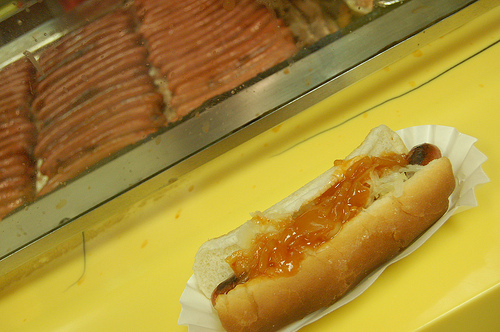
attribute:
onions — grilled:
[225, 152, 422, 277]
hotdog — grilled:
[190, 124, 450, 330]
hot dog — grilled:
[227, 144, 447, 288]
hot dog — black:
[213, 122, 455, 328]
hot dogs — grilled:
[38, 45, 204, 112]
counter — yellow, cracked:
[400, 67, 462, 116]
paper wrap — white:
[453, 127, 488, 209]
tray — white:
[122, 85, 486, 329]